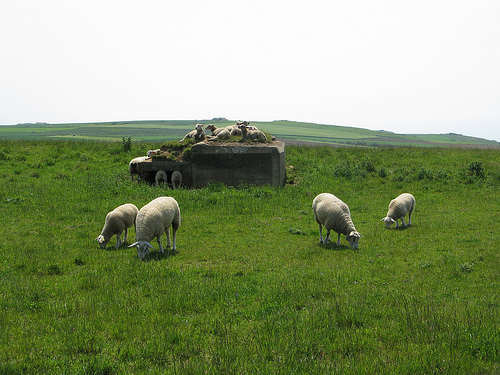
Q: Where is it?
A: This is at the field.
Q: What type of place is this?
A: It is a field.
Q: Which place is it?
A: It is a field.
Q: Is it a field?
A: Yes, it is a field.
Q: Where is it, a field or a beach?
A: It is a field.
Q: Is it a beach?
A: No, it is a field.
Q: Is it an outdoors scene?
A: Yes, it is outdoors.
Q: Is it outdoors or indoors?
A: It is outdoors.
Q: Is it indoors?
A: No, it is outdoors.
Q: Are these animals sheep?
A: Yes, all the animals are sheep.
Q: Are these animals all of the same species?
A: Yes, all the animals are sheep.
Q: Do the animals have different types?
A: No, all the animals are sheep.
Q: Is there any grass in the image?
A: Yes, there is grass.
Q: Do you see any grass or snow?
A: Yes, there is grass.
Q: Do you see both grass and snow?
A: No, there is grass but no snow.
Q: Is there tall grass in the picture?
A: Yes, there is tall grass.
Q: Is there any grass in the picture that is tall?
A: Yes, there is tall grass.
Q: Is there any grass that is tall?
A: Yes, there is grass that is tall.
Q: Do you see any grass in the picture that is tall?
A: Yes, there is grass that is tall.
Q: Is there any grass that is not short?
A: Yes, there is tall grass.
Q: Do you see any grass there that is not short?
A: Yes, there is tall grass.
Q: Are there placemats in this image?
A: No, there are no placemats.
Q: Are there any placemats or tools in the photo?
A: No, there are no placemats or tools.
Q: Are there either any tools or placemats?
A: No, there are no placemats or tools.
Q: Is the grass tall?
A: Yes, the grass is tall.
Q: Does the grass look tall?
A: Yes, the grass is tall.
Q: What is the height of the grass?
A: The grass is tall.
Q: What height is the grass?
A: The grass is tall.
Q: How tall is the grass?
A: The grass is tall.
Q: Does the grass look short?
A: No, the grass is tall.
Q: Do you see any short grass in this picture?
A: No, there is grass but it is tall.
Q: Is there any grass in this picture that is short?
A: No, there is grass but it is tall.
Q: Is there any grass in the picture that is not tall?
A: No, there is grass but it is tall.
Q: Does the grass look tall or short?
A: The grass is tall.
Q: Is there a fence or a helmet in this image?
A: No, there are no fences or helmets.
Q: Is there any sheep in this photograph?
A: Yes, there is a sheep.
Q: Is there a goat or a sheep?
A: Yes, there is a sheep.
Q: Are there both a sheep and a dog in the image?
A: No, there is a sheep but no dogs.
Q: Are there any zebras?
A: No, there are no zebras.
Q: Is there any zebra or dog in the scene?
A: No, there are no zebras or dogs.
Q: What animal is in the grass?
A: The animal is a sheep.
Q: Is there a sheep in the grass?
A: Yes, there is a sheep in the grass.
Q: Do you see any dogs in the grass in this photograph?
A: No, there is a sheep in the grass.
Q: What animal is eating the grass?
A: The sheep is eating the grass.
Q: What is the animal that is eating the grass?
A: The animal is a sheep.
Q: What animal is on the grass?
A: The animal is a sheep.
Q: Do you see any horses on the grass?
A: No, there is a sheep on the grass.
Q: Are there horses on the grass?
A: No, there is a sheep on the grass.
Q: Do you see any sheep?
A: Yes, there is a sheep.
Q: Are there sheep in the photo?
A: Yes, there is a sheep.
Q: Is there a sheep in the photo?
A: Yes, there is a sheep.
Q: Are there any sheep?
A: Yes, there is a sheep.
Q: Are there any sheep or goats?
A: Yes, there is a sheep.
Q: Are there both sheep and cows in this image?
A: No, there is a sheep but no cows.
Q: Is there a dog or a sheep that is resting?
A: Yes, the sheep is resting.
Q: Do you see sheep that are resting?
A: Yes, there is a sheep that is resting.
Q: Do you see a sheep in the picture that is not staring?
A: Yes, there is a sheep that is resting .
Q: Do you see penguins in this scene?
A: No, there are no penguins.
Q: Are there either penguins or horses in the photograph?
A: No, there are no penguins or horses.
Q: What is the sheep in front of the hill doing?
A: The sheep is resting.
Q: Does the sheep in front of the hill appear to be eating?
A: No, the sheep is resting.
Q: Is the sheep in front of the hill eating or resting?
A: The sheep is resting.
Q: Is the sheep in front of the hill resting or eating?
A: The sheep is resting.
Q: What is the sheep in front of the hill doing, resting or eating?
A: The sheep is resting.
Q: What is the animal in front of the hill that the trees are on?
A: The animal is a sheep.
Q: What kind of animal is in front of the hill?
A: The animal is a sheep.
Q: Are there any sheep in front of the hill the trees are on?
A: Yes, there is a sheep in front of the hill.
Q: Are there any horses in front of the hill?
A: No, there is a sheep in front of the hill.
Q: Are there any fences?
A: No, there are no fences.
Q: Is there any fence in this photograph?
A: No, there are no fences.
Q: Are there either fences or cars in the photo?
A: No, there are no fences or cars.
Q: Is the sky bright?
A: Yes, the sky is bright.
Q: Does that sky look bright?
A: Yes, the sky is bright.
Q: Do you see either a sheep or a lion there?
A: Yes, there is a sheep.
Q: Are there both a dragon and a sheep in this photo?
A: No, there is a sheep but no dragons.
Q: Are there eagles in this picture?
A: No, there are no eagles.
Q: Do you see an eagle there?
A: No, there are no eagles.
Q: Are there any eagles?
A: No, there are no eagles.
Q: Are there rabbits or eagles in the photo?
A: No, there are no eagles or rabbits.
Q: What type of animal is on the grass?
A: The animal is a sheep.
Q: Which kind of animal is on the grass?
A: The animal is a sheep.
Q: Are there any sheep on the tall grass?
A: Yes, there is a sheep on the grass.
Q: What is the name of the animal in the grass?
A: The animal is a sheep.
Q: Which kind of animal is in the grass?
A: The animal is a sheep.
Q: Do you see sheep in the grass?
A: Yes, there is a sheep in the grass.